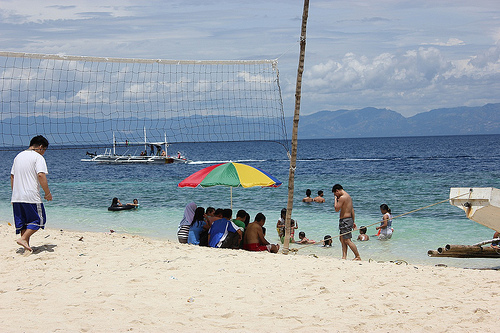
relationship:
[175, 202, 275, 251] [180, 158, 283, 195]
people under umbrella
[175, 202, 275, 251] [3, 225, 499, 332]
people on sand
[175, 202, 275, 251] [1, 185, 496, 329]
people on beach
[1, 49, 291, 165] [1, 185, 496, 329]
net at beach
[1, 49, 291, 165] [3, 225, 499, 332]
net above sand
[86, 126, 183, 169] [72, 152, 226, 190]
boat in water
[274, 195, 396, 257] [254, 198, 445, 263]
people in water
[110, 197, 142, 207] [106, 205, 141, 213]
people on tubes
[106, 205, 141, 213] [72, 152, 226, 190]
tubes in water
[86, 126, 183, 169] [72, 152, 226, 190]
boat on water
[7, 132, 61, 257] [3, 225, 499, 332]
man on sand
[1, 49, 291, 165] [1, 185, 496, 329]
net on beach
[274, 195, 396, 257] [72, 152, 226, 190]
people in water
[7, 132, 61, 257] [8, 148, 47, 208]
man wears top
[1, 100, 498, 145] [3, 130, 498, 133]
mountains in background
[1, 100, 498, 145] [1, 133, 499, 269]
mountains by ocean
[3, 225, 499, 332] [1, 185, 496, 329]
sand on beach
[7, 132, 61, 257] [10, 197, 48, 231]
man in shorts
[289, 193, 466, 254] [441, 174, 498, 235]
rope anchoring boat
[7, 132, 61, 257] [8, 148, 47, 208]
man in top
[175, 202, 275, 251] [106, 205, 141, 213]
people with tubes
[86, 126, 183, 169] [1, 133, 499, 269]
boat in ocean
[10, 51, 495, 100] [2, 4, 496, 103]
clouds in sky